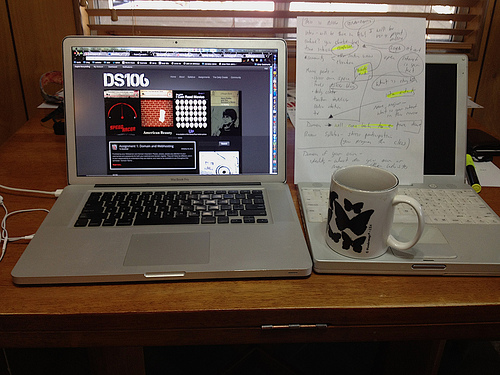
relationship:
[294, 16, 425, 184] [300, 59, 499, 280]
paper covering laptop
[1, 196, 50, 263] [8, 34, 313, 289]
cable to a computer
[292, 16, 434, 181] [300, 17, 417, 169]
paper with notes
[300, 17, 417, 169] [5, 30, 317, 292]
notes propped on laptop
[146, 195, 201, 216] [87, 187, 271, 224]
black keys on keyboard